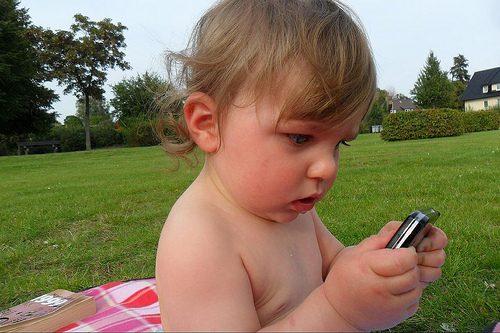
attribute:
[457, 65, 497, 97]
roof — BLACK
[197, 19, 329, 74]
hair — brown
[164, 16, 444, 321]
child — one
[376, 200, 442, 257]
phone — silver, black, cell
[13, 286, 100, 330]
book — one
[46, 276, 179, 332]
cloth — red, white, pink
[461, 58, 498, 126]
house — black, yellow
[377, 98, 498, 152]
hedges — large, green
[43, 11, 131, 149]
tree — green, tall, oak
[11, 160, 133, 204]
grass — green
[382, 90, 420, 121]
house — gray, white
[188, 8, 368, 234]
baby — drooling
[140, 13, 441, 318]
baby — sitting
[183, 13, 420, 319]
baby — one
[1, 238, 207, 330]
blanket — red, white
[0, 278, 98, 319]
title — is "1999"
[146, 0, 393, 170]
hair — curly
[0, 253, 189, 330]
blanket — checkered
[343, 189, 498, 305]
cell phone — black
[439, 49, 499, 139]
roof — black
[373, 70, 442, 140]
roof — grey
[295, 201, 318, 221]
drowl — babies lips